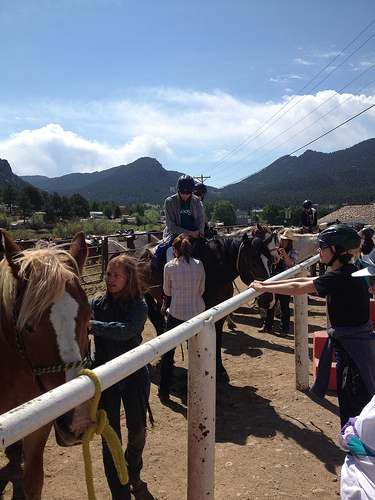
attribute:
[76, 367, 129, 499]
rope — yellow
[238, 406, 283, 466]
shade — pictured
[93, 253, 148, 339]
person — pictured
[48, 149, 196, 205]
hill — pictured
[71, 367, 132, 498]
rope — yellow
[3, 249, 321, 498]
pole — white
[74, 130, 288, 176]
cloud — pictured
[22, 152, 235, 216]
hill — pictured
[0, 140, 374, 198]
bluffs — distant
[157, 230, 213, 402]
person — pictured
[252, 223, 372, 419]
person — pictured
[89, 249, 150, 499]
person — pictured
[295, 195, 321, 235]
person — pictured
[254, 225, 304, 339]
person — pictured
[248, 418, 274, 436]
shade — pictured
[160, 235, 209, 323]
person — pictured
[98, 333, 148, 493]
pants — brown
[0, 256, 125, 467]
horse — brown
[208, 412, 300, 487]
floor — pictured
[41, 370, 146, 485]
rope — yellow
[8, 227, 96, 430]
horse — brown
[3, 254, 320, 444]
pole — white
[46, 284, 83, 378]
marking — white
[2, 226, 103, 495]
horse — brown